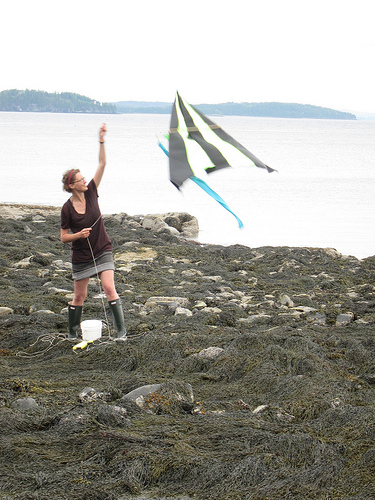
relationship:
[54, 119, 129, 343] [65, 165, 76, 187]
woman wearing headband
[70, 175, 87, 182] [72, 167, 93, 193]
glasses on face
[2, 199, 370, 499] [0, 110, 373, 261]
cliff by water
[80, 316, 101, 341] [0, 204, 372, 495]
bucket on ground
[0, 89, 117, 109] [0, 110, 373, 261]
trees by water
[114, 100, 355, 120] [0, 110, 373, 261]
land by water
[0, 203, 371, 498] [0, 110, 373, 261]
land by water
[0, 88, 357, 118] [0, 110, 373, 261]
land by water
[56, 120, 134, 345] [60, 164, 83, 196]
girl has hair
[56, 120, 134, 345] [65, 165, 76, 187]
girl wearing headband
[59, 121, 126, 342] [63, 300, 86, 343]
girl wearing boot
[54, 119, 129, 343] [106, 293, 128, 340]
woman wearing boot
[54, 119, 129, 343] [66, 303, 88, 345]
woman wearing boot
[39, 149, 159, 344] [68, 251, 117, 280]
woman wearing skirt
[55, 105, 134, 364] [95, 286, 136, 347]
woman wearing black boot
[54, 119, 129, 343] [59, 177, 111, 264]
woman wearing shirt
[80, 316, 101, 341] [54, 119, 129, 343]
bucket next to woman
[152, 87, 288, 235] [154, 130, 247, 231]
kite with tail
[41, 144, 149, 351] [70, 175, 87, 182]
woman wearing glasses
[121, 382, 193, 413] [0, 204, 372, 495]
rock on ground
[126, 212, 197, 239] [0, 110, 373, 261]
rocks in water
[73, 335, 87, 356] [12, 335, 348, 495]
handle on ground